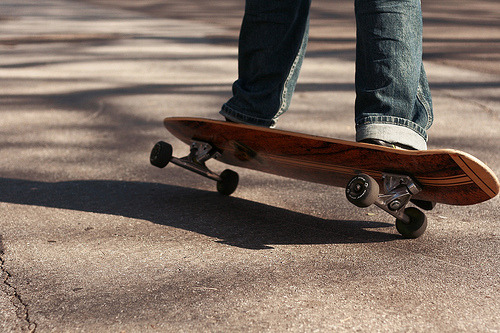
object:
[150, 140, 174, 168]
wheel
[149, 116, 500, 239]
skateboard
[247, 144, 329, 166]
back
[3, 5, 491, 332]
street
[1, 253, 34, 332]
crack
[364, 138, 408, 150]
feet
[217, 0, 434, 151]
jeans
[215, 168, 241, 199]
wheel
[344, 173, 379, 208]
wheel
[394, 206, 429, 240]
wheel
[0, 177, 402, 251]
shadow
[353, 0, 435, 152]
leg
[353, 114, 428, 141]
seams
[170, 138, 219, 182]
axle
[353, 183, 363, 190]
bolt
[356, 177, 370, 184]
writing